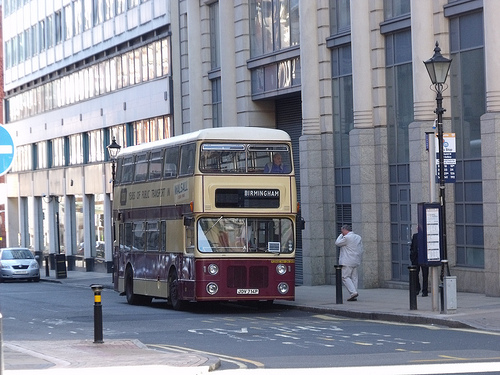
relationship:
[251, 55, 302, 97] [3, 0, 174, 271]
window on building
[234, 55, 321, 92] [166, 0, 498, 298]
window of building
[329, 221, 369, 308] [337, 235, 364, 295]
man wearing white suit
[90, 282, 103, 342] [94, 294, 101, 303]
pole has yellow sticker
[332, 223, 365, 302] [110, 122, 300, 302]
man riding bus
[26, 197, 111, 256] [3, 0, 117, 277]
windows on building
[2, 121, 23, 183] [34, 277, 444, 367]
sign on street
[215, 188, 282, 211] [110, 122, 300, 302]
black rectangle on bus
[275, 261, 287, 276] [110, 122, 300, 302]
headlamp on bus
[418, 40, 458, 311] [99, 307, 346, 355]
lamp post on a street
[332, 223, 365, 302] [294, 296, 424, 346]
man walking on street